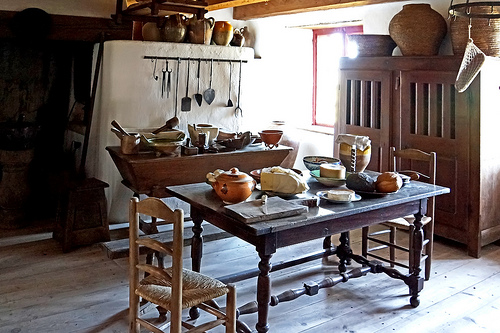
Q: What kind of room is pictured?
A: It is a kitchen.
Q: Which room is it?
A: It is a kitchen.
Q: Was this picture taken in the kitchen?
A: Yes, it was taken in the kitchen.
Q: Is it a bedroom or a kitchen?
A: It is a kitchen.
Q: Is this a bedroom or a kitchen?
A: It is a kitchen.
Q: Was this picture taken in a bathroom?
A: No, the picture was taken in a kitchen.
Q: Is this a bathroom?
A: No, it is a kitchen.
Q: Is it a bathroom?
A: No, it is a kitchen.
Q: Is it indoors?
A: Yes, it is indoors.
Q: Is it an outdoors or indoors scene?
A: It is indoors.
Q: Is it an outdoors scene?
A: No, it is indoors.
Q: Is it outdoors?
A: No, it is indoors.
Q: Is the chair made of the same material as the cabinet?
A: Yes, both the chair and the cabinet are made of wood.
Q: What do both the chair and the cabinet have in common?
A: The material, both the chair and the cabinet are wooden.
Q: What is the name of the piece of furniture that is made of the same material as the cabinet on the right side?
A: The piece of furniture is a chair.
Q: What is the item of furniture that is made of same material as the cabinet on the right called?
A: The piece of furniture is a chair.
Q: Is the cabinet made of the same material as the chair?
A: Yes, both the cabinet and the chair are made of wood.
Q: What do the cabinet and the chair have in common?
A: The material, both the cabinet and the chair are wooden.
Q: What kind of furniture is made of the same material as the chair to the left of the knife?
A: The cabinet is made of the same material as the chair.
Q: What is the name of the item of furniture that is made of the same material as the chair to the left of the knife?
A: The piece of furniture is a cabinet.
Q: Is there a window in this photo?
A: Yes, there is a window.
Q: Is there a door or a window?
A: Yes, there is a window.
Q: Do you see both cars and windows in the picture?
A: No, there is a window but no cars.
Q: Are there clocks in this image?
A: No, there are no clocks.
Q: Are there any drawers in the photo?
A: No, there are no drawers.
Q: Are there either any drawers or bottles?
A: No, there are no drawers or bottles.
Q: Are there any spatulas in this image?
A: Yes, there is a spatula.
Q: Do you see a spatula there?
A: Yes, there is a spatula.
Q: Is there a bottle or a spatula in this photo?
A: Yes, there is a spatula.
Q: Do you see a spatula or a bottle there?
A: Yes, there is a spatula.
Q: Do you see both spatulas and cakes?
A: No, there is a spatula but no cakes.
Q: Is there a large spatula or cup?
A: Yes, there is a large spatula.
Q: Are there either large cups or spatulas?
A: Yes, there is a large spatula.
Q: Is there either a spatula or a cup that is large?
A: Yes, the spatula is large.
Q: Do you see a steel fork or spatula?
A: Yes, there is a steel spatula.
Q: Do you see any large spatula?
A: Yes, there is a large spatula.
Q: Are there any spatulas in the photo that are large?
A: Yes, there is a spatula that is large.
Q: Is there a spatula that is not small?
A: Yes, there is a large spatula.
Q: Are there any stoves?
A: No, there are no stoves.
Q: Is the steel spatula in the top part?
A: Yes, the spatula is in the top of the image.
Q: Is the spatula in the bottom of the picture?
A: No, the spatula is in the top of the image.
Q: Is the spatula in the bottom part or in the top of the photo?
A: The spatula is in the top of the image.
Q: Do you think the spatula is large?
A: Yes, the spatula is large.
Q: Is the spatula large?
A: Yes, the spatula is large.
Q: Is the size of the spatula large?
A: Yes, the spatula is large.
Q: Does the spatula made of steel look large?
A: Yes, the spatula is large.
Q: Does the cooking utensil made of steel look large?
A: Yes, the spatula is large.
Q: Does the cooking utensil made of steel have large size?
A: Yes, the spatula is large.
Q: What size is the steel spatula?
A: The spatula is large.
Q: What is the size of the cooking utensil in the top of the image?
A: The spatula is large.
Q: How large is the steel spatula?
A: The spatula is large.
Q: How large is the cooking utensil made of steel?
A: The spatula is large.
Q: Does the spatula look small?
A: No, the spatula is large.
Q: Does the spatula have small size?
A: No, the spatula is large.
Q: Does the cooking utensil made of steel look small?
A: No, the spatula is large.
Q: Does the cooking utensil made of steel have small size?
A: No, the spatula is large.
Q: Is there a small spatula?
A: No, there is a spatula but it is large.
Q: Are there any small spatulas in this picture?
A: No, there is a spatula but it is large.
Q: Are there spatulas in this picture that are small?
A: No, there is a spatula but it is large.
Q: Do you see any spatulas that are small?
A: No, there is a spatula but it is large.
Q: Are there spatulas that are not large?
A: No, there is a spatula but it is large.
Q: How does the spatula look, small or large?
A: The spatula is large.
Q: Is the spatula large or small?
A: The spatula is large.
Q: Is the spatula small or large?
A: The spatula is large.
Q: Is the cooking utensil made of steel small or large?
A: The spatula is large.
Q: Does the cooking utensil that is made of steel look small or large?
A: The spatula is large.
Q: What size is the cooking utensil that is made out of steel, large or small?
A: The spatula is large.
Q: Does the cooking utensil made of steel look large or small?
A: The spatula is large.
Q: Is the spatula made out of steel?
A: Yes, the spatula is made of steel.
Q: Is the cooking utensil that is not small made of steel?
A: Yes, the spatula is made of steel.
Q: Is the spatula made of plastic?
A: No, the spatula is made of steel.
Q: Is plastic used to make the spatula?
A: No, the spatula is made of steel.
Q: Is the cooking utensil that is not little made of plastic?
A: No, the spatula is made of steel.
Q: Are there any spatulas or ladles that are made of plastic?
A: No, there is a spatula but it is made of steel.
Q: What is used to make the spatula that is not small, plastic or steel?
A: The spatula is made of steel.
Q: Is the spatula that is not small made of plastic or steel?
A: The spatula is made of steel.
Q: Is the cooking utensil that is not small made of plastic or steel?
A: The spatula is made of steel.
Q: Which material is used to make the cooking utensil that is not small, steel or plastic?
A: The spatula is made of steel.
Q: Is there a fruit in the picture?
A: No, there are no fruits.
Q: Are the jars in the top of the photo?
A: Yes, the jars are in the top of the image.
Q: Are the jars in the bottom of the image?
A: No, the jars are in the top of the image.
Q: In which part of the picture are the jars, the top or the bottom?
A: The jars are in the top of the image.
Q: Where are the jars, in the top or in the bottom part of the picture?
A: The jars are in the top of the image.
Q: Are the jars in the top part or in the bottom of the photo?
A: The jars are in the top of the image.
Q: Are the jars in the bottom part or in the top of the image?
A: The jars are in the top of the image.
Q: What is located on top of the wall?
A: The jars are on top of the wall.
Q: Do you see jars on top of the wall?
A: Yes, there are jars on top of the wall.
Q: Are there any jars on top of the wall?
A: Yes, there are jars on top of the wall.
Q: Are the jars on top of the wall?
A: Yes, the jars are on top of the wall.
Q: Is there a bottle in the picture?
A: No, there are no bottles.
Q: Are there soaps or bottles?
A: No, there are no bottles or soaps.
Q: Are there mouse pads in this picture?
A: No, there are no mouse pads.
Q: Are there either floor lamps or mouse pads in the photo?
A: No, there are no mouse pads or floor lamps.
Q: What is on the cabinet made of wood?
A: The basket is on the cabinet.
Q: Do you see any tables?
A: Yes, there is a table.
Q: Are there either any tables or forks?
A: Yes, there is a table.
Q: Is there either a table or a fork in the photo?
A: Yes, there is a table.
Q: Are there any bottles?
A: No, there are no bottles.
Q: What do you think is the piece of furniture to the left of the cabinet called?
A: The piece of furniture is a table.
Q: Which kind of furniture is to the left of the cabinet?
A: The piece of furniture is a table.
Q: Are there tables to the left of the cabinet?
A: Yes, there is a table to the left of the cabinet.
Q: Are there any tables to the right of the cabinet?
A: No, the table is to the left of the cabinet.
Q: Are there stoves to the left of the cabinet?
A: No, there is a table to the left of the cabinet.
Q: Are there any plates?
A: Yes, there is a plate.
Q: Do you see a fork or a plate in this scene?
A: Yes, there is a plate.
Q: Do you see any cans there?
A: No, there are no cans.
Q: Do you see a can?
A: No, there are no cans.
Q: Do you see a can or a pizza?
A: No, there are no cans or pizzas.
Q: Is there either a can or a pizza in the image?
A: No, there are no cans or pizzas.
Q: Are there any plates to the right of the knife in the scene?
A: Yes, there is a plate to the right of the knife.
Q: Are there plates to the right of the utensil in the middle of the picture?
A: Yes, there is a plate to the right of the knife.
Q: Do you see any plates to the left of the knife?
A: No, the plate is to the right of the knife.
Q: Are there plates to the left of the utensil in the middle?
A: No, the plate is to the right of the knife.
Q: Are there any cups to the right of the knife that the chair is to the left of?
A: No, there is a plate to the right of the knife.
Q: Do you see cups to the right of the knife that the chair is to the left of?
A: No, there is a plate to the right of the knife.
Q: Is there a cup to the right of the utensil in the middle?
A: No, there is a plate to the right of the knife.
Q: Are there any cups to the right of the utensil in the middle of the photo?
A: No, there is a plate to the right of the knife.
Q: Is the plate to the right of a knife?
A: Yes, the plate is to the right of a knife.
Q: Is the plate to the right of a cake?
A: No, the plate is to the right of a knife.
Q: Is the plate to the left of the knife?
A: No, the plate is to the right of the knife.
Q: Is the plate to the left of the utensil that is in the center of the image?
A: No, the plate is to the right of the knife.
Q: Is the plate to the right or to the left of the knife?
A: The plate is to the right of the knife.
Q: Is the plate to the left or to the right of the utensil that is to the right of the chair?
A: The plate is to the right of the knife.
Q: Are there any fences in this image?
A: No, there are no fences.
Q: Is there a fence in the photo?
A: No, there are no fences.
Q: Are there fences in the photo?
A: No, there are no fences.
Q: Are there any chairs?
A: Yes, there is a chair.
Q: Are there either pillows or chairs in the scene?
A: Yes, there is a chair.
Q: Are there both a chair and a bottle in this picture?
A: No, there is a chair but no bottles.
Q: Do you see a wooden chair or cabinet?
A: Yes, there is a wood chair.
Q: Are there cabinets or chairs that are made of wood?
A: Yes, the chair is made of wood.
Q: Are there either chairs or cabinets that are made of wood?
A: Yes, the chair is made of wood.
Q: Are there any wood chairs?
A: Yes, there is a wood chair.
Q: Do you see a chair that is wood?
A: Yes, there is a wood chair.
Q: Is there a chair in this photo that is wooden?
A: Yes, there is a chair that is wooden.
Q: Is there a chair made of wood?
A: Yes, there is a chair that is made of wood.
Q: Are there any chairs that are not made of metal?
A: Yes, there is a chair that is made of wood.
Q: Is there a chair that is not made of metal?
A: Yes, there is a chair that is made of wood.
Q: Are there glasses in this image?
A: No, there are no glasses.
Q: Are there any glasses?
A: No, there are no glasses.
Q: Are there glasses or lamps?
A: No, there are no glasses or lamps.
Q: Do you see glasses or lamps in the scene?
A: No, there are no glasses or lamps.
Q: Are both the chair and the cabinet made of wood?
A: Yes, both the chair and the cabinet are made of wood.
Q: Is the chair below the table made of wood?
A: Yes, the chair is made of wood.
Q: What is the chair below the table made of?
A: The chair is made of wood.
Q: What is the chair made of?
A: The chair is made of wood.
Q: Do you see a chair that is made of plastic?
A: No, there is a chair but it is made of wood.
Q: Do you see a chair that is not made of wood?
A: No, there is a chair but it is made of wood.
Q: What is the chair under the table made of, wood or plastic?
A: The chair is made of wood.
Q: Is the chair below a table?
A: Yes, the chair is below a table.